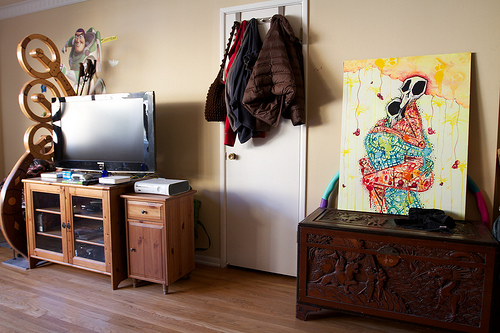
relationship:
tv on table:
[57, 98, 151, 164] [39, 183, 115, 223]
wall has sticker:
[153, 21, 165, 33] [82, 42, 88, 48]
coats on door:
[236, 39, 290, 90] [260, 150, 275, 170]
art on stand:
[381, 94, 455, 150] [327, 250, 385, 276]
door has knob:
[260, 150, 275, 170] [228, 153, 236, 159]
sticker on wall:
[82, 42, 88, 48] [153, 21, 165, 33]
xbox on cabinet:
[138, 184, 170, 190] [129, 203, 174, 268]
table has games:
[39, 183, 115, 223] [78, 210, 97, 251]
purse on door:
[211, 92, 217, 109] [260, 150, 275, 170]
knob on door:
[228, 153, 236, 159] [260, 150, 275, 170]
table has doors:
[39, 183, 115, 223] [54, 217, 77, 238]